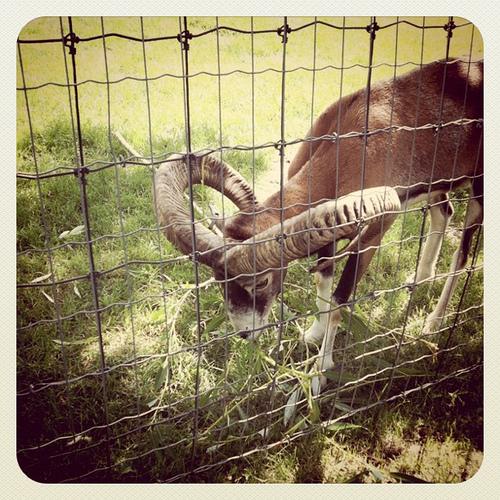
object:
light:
[458, 56, 482, 86]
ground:
[26, 31, 470, 478]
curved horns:
[152, 153, 401, 276]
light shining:
[262, 416, 482, 485]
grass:
[16, 16, 484, 485]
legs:
[304, 233, 385, 388]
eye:
[251, 278, 268, 293]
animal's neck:
[261, 157, 357, 223]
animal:
[152, 56, 484, 395]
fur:
[363, 154, 400, 174]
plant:
[171, 304, 382, 426]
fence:
[16, 16, 484, 484]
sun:
[123, 53, 276, 118]